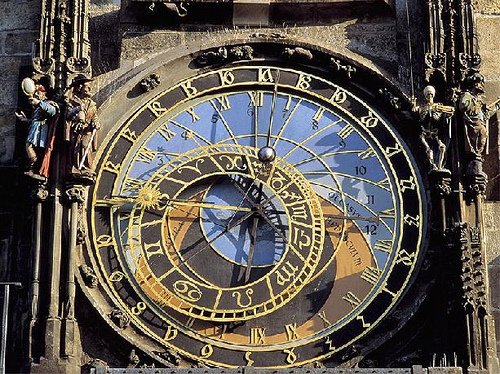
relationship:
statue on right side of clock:
[408, 84, 455, 180] [68, 41, 450, 365]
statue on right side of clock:
[456, 70, 499, 187] [68, 41, 450, 365]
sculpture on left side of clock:
[62, 74, 100, 185] [88, 64, 431, 367]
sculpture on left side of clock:
[13, 76, 59, 184] [88, 64, 431, 367]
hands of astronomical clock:
[107, 161, 303, 308] [63, 48, 433, 366]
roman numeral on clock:
[307, 102, 326, 124] [68, 41, 450, 365]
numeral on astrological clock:
[358, 264, 384, 285] [74, 33, 440, 369]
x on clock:
[317, 311, 332, 328] [88, 64, 431, 367]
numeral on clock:
[370, 231, 399, 256] [68, 41, 450, 365]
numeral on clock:
[282, 319, 302, 340] [61, 46, 419, 372]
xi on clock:
[335, 284, 369, 314] [68, 41, 450, 365]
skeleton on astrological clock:
[409, 59, 492, 207] [74, 33, 440, 369]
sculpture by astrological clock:
[62, 74, 100, 185] [83, 43, 440, 371]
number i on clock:
[283, 93, 293, 110] [88, 64, 431, 367]